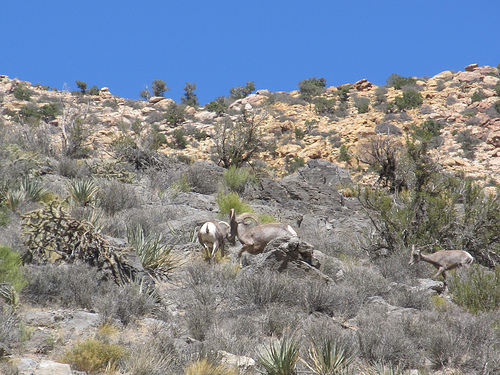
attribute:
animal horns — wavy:
[405, 237, 479, 287]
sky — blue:
[0, 1, 497, 108]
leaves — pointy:
[258, 330, 298, 373]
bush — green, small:
[218, 164, 260, 218]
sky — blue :
[124, 19, 271, 72]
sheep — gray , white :
[196, 200, 330, 268]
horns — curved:
[222, 202, 246, 232]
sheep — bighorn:
[217, 204, 298, 265]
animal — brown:
[407, 242, 475, 284]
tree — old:
[8, 171, 151, 301]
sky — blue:
[5, 11, 477, 94]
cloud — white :
[224, 24, 295, 89]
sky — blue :
[7, 9, 498, 111]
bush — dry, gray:
[174, 279, 221, 341]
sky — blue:
[3, 3, 498, 93]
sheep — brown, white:
[188, 218, 240, 266]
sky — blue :
[12, 7, 473, 52]